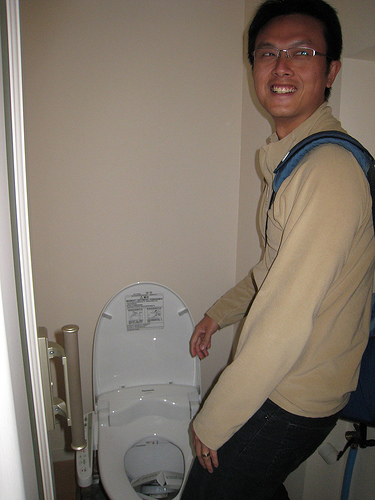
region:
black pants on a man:
[177, 386, 367, 497]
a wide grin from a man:
[252, 78, 316, 102]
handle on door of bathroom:
[57, 324, 90, 452]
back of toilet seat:
[87, 279, 203, 395]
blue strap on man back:
[272, 128, 373, 197]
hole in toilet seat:
[120, 431, 192, 498]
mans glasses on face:
[251, 47, 315, 62]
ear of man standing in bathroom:
[331, 57, 339, 88]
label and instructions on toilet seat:
[123, 292, 165, 334]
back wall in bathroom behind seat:
[23, 1, 245, 471]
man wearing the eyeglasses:
[240, 40, 323, 71]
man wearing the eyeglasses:
[242, 36, 323, 71]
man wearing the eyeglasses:
[247, 35, 334, 71]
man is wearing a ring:
[184, 438, 222, 474]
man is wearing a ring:
[184, 438, 220, 469]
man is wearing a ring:
[189, 440, 218, 459]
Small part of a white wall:
[40, 239, 54, 258]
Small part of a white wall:
[49, 270, 72, 295]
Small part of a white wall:
[120, 250, 156, 274]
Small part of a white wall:
[217, 221, 259, 256]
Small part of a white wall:
[178, 218, 219, 250]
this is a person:
[178, 13, 370, 498]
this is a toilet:
[57, 282, 205, 495]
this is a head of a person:
[241, 6, 343, 132]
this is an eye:
[286, 35, 321, 69]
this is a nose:
[271, 58, 287, 81]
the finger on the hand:
[206, 441, 225, 466]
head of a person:
[223, 6, 351, 126]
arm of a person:
[214, 264, 324, 440]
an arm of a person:
[210, 262, 341, 417]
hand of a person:
[171, 294, 226, 367]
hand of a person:
[173, 415, 237, 490]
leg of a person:
[187, 399, 282, 498]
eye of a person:
[255, 30, 285, 75]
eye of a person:
[292, 30, 322, 68]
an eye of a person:
[252, 35, 279, 68]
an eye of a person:
[284, 36, 319, 71]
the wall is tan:
[132, 64, 159, 89]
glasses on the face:
[249, 46, 312, 64]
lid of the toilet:
[103, 293, 184, 389]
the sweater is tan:
[294, 335, 339, 367]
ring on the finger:
[198, 446, 211, 459]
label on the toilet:
[120, 287, 164, 332]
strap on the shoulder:
[305, 131, 355, 155]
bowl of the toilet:
[134, 457, 175, 495]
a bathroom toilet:
[119, 299, 216, 489]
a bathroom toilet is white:
[76, 277, 223, 482]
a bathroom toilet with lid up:
[60, 292, 216, 497]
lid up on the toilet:
[79, 247, 229, 419]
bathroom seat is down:
[98, 406, 171, 494]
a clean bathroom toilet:
[106, 276, 234, 466]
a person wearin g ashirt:
[197, 228, 360, 472]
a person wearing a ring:
[188, 437, 213, 461]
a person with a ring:
[202, 402, 234, 488]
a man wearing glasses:
[181, 7, 372, 497]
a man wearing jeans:
[191, 0, 373, 499]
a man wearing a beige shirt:
[174, 5, 373, 497]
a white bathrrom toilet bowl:
[84, 280, 222, 498]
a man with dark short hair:
[178, 2, 371, 498]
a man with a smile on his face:
[172, 2, 373, 499]